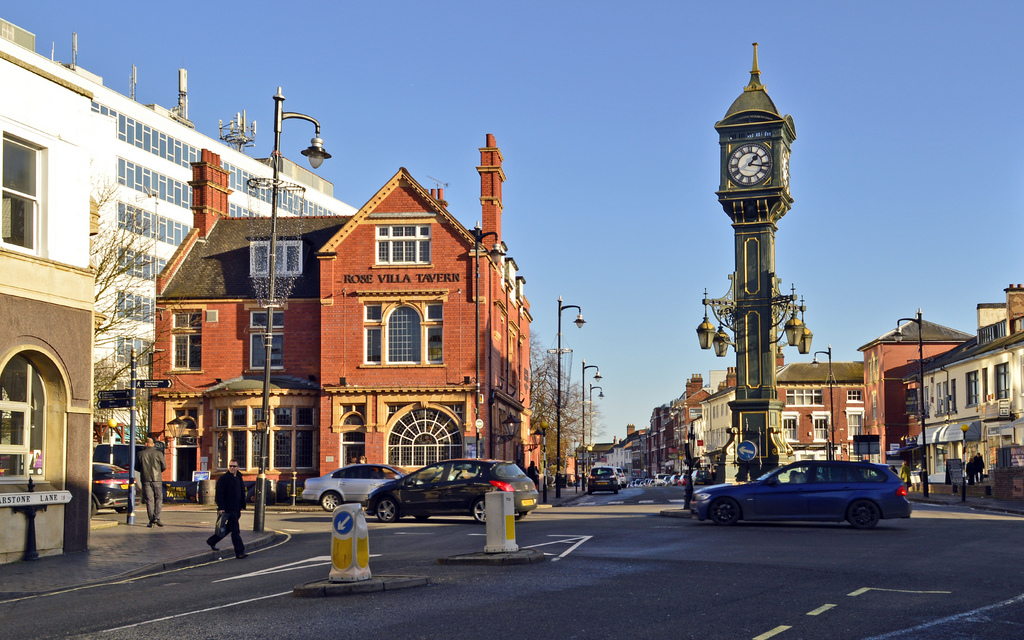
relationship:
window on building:
[170, 308, 203, 372] [133, 257, 343, 458]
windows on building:
[375, 381, 481, 470] [293, 223, 497, 468]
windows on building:
[215, 391, 326, 476] [167, 262, 377, 507]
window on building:
[150, 324, 205, 353] [154, 281, 349, 465]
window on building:
[271, 236, 310, 273] [187, 206, 382, 509]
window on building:
[377, 219, 403, 272] [327, 163, 505, 486]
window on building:
[375, 223, 434, 267] [312, 162, 516, 536]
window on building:
[375, 223, 434, 267] [305, 147, 506, 469]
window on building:
[375, 223, 434, 267] [327, 163, 505, 486]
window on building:
[362, 324, 391, 368] [305, 156, 498, 502]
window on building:
[420, 312, 444, 364] [310, 158, 492, 535]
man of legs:
[198, 465, 257, 569] [200, 517, 252, 559]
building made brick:
[153, 139, 542, 485] [453, 314, 464, 353]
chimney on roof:
[181, 145, 234, 228] [177, 210, 337, 290]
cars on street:
[289, 448, 557, 529] [490, 508, 992, 627]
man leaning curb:
[205, 457, 250, 559] [327, 502, 375, 583]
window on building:
[153, 141, 540, 474] [153, 139, 542, 485]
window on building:
[360, 294, 453, 372] [142, 132, 549, 500]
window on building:
[353, 288, 449, 371] [153, 139, 542, 485]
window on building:
[2, 137, 46, 244] [10, 18, 365, 524]